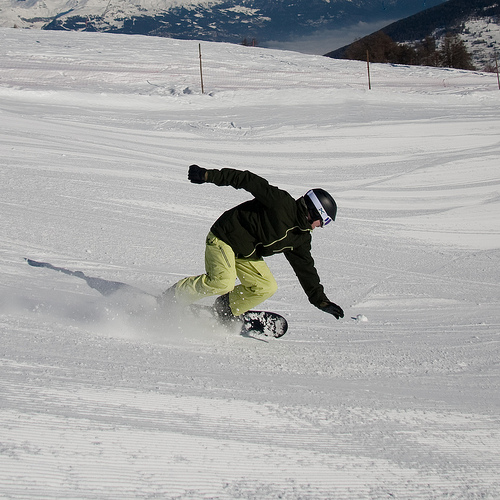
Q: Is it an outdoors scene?
A: Yes, it is outdoors.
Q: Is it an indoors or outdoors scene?
A: It is outdoors.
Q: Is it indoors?
A: No, it is outdoors.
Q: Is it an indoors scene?
A: No, it is outdoors.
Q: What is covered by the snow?
A: The mountain is covered by the snow.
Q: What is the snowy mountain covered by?
A: The mountain is covered by the snow.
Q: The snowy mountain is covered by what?
A: The mountain is covered by the snow.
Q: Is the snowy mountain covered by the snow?
A: Yes, the mountain is covered by the snow.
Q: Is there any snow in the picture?
A: Yes, there is snow.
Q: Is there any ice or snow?
A: Yes, there is snow.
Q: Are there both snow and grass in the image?
A: No, there is snow but no grass.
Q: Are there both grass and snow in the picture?
A: No, there is snow but no grass.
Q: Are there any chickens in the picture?
A: No, there are no chickens.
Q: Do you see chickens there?
A: No, there are no chickens.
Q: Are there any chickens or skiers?
A: No, there are no chickens or skiers.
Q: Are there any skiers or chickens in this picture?
A: No, there are no chickens or skiers.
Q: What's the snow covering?
A: The snow is covering the mountain.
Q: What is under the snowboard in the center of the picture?
A: The snow is under the snow board.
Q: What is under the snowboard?
A: The snow is under the snow board.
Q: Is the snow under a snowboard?
A: Yes, the snow is under a snowboard.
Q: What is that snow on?
A: The snow is on the snowboard.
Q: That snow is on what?
A: The snow is on the snowboard.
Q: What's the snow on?
A: The snow is on the snowboard.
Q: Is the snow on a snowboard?
A: Yes, the snow is on a snowboard.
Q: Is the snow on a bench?
A: No, the snow is on a snowboard.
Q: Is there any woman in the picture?
A: No, there are no women.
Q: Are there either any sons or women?
A: No, there are no women or sons.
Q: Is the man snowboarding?
A: Yes, the man is snowboarding.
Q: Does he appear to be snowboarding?
A: Yes, the man is snowboarding.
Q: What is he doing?
A: The man is snowboarding.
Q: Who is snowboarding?
A: The man is snowboarding.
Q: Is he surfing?
A: No, the man is snowboarding.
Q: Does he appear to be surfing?
A: No, the man is snowboarding.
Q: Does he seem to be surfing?
A: No, the man is snowboarding.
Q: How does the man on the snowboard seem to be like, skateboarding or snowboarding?
A: The man is snowboarding.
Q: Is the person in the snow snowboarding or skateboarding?
A: The man is snowboarding.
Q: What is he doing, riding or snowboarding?
A: The man is snowboarding.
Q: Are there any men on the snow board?
A: Yes, there is a man on the snow board.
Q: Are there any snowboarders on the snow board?
A: No, there is a man on the snow board.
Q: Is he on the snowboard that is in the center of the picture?
A: Yes, the man is on the snowboard.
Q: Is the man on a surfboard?
A: No, the man is on the snowboard.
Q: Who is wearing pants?
A: The man is wearing pants.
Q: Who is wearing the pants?
A: The man is wearing pants.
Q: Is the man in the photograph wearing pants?
A: Yes, the man is wearing pants.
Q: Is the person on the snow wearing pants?
A: Yes, the man is wearing pants.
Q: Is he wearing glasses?
A: No, the man is wearing pants.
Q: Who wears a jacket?
A: The man wears a jacket.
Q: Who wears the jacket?
A: The man wears a jacket.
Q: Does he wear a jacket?
A: Yes, the man wears a jacket.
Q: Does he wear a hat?
A: No, the man wears a jacket.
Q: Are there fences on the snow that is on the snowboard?
A: No, there is a man on the snow.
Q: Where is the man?
A: The man is in the snow.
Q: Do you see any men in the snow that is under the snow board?
A: Yes, there is a man in the snow.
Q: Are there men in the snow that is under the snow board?
A: Yes, there is a man in the snow.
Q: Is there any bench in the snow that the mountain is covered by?
A: No, there is a man in the snow.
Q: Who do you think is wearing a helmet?
A: The man is wearing a helmet.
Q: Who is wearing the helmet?
A: The man is wearing a helmet.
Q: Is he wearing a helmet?
A: Yes, the man is wearing a helmet.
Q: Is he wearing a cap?
A: No, the man is wearing a helmet.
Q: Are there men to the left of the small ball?
A: Yes, there is a man to the left of the ball.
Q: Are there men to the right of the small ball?
A: No, the man is to the left of the ball.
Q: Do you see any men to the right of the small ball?
A: No, the man is to the left of the ball.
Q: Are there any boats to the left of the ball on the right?
A: No, there is a man to the left of the ball.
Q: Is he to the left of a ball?
A: Yes, the man is to the left of a ball.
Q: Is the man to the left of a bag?
A: No, the man is to the left of a ball.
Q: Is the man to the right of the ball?
A: No, the man is to the left of the ball.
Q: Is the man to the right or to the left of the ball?
A: The man is to the left of the ball.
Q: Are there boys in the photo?
A: No, there are no boys.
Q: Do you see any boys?
A: No, there are no boys.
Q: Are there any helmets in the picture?
A: Yes, there is a helmet.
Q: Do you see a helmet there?
A: Yes, there is a helmet.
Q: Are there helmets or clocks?
A: Yes, there is a helmet.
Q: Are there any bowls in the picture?
A: No, there are no bowls.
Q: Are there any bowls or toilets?
A: No, there are no bowls or toilets.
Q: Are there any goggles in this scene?
A: Yes, there are goggles.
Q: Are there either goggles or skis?
A: Yes, there are goggles.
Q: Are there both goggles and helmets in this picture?
A: Yes, there are both goggles and a helmet.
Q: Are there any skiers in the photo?
A: No, there are no skiers.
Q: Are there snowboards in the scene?
A: Yes, there is a snowboard.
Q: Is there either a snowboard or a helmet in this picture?
A: Yes, there is a snowboard.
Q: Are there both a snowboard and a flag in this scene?
A: No, there is a snowboard but no flags.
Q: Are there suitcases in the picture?
A: No, there are no suitcases.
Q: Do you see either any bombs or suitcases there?
A: No, there are no suitcases or bombs.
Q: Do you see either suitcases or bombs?
A: No, there are no suitcases or bombs.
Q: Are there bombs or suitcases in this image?
A: No, there are no suitcases or bombs.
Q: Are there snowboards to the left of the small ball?
A: Yes, there is a snowboard to the left of the ball.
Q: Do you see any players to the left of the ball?
A: No, there is a snowboard to the left of the ball.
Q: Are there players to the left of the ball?
A: No, there is a snowboard to the left of the ball.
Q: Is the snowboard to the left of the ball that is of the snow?
A: Yes, the snowboard is to the left of the ball.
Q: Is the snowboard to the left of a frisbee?
A: No, the snowboard is to the left of the ball.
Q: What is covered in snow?
A: The snowboard is covered in snow.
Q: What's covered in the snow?
A: The snowboard is covered in snow.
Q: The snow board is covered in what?
A: The snow board is covered in snow.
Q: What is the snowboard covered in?
A: The snow board is covered in snow.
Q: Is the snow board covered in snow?
A: Yes, the snow board is covered in snow.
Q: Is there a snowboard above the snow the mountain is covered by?
A: Yes, there is a snowboard above the snow.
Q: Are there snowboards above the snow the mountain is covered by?
A: Yes, there is a snowboard above the snow.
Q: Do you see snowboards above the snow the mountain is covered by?
A: Yes, there is a snowboard above the snow.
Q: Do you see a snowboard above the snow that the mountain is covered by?
A: Yes, there is a snowboard above the snow.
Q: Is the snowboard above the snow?
A: Yes, the snowboard is above the snow.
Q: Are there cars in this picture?
A: No, there are no cars.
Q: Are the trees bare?
A: Yes, the trees are bare.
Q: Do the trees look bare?
A: Yes, the trees are bare.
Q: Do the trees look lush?
A: No, the trees are bare.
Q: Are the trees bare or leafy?
A: The trees are bare.